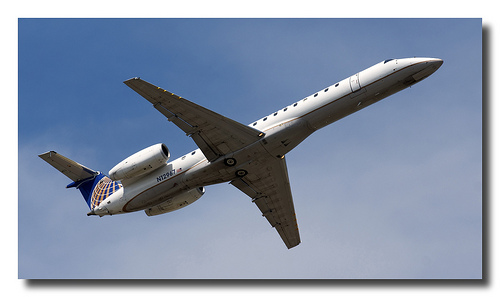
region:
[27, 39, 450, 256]
Plane in the sky.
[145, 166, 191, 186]
Numbers on the plane.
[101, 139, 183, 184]
Engine on the plane.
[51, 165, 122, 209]
Circle with lines on the tail.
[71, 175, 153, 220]
Background of the tail is blue.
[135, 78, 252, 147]
The wing is white.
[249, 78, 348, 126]
Windows on the plane.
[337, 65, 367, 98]
Door on the plane.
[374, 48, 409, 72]
Windshield on the plane.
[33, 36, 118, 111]
The sky is blue.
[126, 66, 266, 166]
the wing of a plane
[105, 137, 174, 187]
the engine of a plane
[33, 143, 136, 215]
the tail of a plane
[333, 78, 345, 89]
a window on the plane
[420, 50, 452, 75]
the nose of a plane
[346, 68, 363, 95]
a door on the plane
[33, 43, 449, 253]
a plane in the sky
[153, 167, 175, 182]
writing on the plane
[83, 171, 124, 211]
a logo on the tail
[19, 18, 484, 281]
a clear blue sky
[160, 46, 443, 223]
bottom of flying plane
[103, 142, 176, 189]
jet engine on plane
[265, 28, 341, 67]
blue of daytime sky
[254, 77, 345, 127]
windows on side of plane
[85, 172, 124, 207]
airline logo on tail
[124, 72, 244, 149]
wing on side of plane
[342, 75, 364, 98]
door on side of plane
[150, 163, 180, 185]
letter and numbers on plane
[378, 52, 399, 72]
windshield on plane cockpit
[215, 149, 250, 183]
wheels of landing gear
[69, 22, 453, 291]
an airplane in the sky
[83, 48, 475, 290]
a large airplane in the sky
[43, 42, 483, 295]
a large airplane flying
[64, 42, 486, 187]
a large passenger airplane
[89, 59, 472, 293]
a large passenger airplane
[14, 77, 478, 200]
a large white airplane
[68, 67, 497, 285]
a large plane in the sky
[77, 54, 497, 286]
a large passenger plane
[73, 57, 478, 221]
a white passenger plane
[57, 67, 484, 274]
a large white passenger plane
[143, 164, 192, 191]
Airplane with american flag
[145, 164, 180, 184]
Airplane with N12967 on it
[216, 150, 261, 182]
Airplane with wheels folded under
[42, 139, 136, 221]
Airplane with blue and gold tail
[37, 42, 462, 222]
Airplane ascending into sky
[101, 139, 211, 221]
Airplane with twin turbo jets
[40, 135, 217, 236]
Airplane with Contenental logo on it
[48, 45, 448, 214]
Airplane flying in sky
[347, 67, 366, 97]
Airplane with a door on the side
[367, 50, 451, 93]
Airplane with a white nose